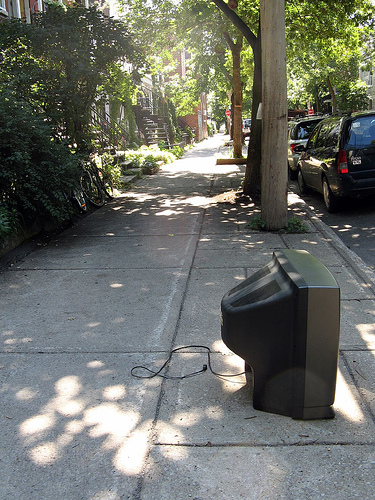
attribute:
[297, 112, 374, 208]
car — big, stopped, dark, new, parked, black, blue, stationed, motionless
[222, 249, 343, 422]
television — grey, busted, old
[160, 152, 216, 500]
roadside — concrete, long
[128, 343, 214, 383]
cable — black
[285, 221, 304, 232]
grass — green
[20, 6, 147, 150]
tree — green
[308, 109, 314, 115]
sign — red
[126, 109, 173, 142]
steps — iron, dark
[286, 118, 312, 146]
car — grey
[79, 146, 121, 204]
bicyle — parked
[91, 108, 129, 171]
rod — iron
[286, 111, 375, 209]
cars — stopped, parked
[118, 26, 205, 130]
houses — aligned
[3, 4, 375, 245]
neigborhood — nice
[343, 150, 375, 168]
trunk — black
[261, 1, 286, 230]
pole — beige, wooden